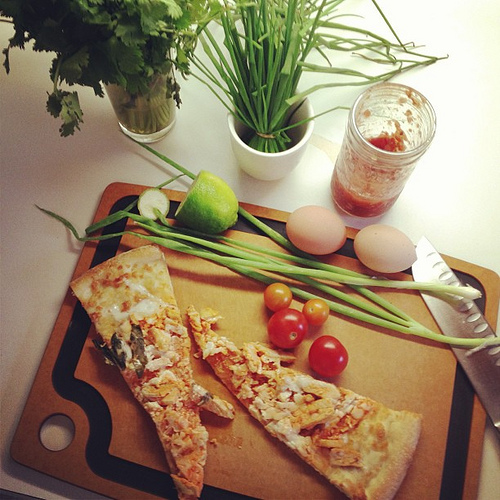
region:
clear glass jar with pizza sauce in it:
[347, 76, 442, 222]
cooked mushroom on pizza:
[96, 326, 153, 391]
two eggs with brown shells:
[285, 199, 434, 281]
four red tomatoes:
[263, 281, 359, 390]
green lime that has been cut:
[171, 160, 256, 274]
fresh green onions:
[78, 180, 473, 370]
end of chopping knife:
[411, 216, 496, 353]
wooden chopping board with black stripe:
[28, 154, 493, 453]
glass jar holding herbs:
[56, 3, 247, 174]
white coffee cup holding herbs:
[204, 2, 332, 199]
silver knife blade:
[414, 236, 498, 423]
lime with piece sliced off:
[173, 171, 239, 231]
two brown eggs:
[283, 205, 417, 272]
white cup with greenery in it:
[161, 3, 423, 185]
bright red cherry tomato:
[266, 307, 307, 351]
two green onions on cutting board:
[36, 205, 496, 347]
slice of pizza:
[75, 244, 217, 496]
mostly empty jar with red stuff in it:
[332, 83, 438, 220]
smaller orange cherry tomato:
[304, 299, 330, 325]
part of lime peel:
[138, 188, 168, 218]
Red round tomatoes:
[251, 281, 375, 373]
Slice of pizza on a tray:
[179, 310, 432, 498]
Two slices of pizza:
[55, 249, 402, 498]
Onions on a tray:
[93, 195, 455, 359]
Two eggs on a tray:
[277, 189, 429, 276]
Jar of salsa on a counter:
[333, 80, 444, 226]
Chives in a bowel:
[206, 41, 318, 198]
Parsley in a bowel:
[33, 11, 207, 157]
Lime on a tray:
[158, 172, 253, 242]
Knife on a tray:
[391, 210, 499, 392]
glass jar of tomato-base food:
[332, 79, 439, 224]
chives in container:
[215, 3, 322, 190]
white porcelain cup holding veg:
[225, 88, 316, 188]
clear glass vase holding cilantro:
[95, 58, 183, 145]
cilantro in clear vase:
[0, 1, 197, 82]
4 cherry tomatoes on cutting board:
[259, 279, 351, 381]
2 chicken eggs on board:
[284, 203, 419, 278]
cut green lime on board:
[132, 170, 239, 239]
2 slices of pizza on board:
[73, 241, 425, 496]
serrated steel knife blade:
[414, 237, 497, 434]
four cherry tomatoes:
[256, 282, 348, 374]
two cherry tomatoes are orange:
[254, 275, 331, 322]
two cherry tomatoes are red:
[255, 302, 347, 367]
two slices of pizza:
[65, 258, 434, 485]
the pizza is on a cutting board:
[15, 182, 495, 494]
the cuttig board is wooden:
[23, 175, 493, 486]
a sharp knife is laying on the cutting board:
[396, 235, 498, 398]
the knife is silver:
[397, 230, 498, 387]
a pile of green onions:
[67, 179, 498, 354]